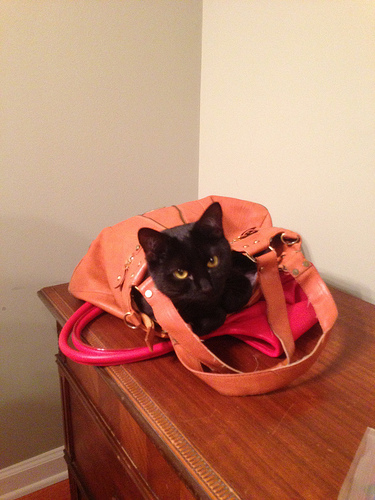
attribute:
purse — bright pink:
[54, 266, 317, 367]